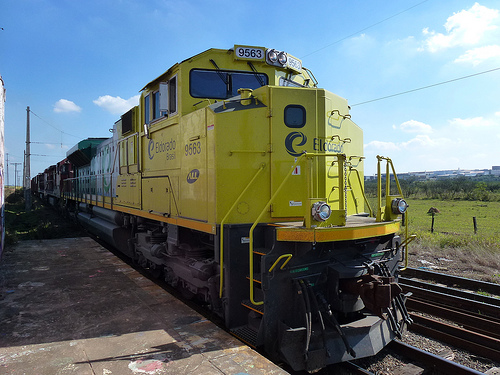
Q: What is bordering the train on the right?
A: Grass.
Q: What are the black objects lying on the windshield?
A: Windshield wipers.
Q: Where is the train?
A: On the railroad track.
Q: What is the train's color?
A: Yellow.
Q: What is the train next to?
A: A brown platform.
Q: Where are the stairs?
A: Front of the train engine.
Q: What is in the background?
A: Grass.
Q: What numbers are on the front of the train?
A: 9563.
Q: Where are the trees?
A: To the train's left.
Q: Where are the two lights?
A: The front of the train.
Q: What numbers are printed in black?
A: 9563.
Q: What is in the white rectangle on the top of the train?
A: Number.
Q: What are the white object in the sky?
A: Clouds.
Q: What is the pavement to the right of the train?
A: Sidewalk.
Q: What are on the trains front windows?
A: Wipers.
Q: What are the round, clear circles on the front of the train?
A: Head lights.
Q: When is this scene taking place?
A: Daytime.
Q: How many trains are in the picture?
A: One.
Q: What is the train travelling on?
A: Train tracks.